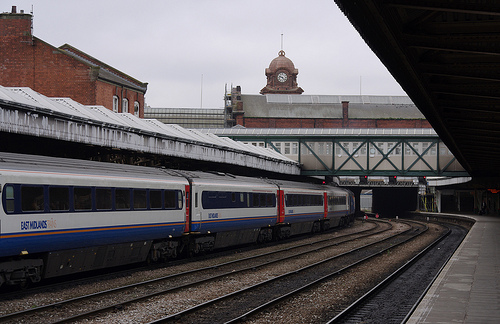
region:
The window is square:
[18, 183, 48, 215]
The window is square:
[43, 177, 73, 213]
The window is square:
[70, 181, 97, 212]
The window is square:
[90, 181, 117, 215]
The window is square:
[113, 185, 131, 213]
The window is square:
[130, 181, 155, 211]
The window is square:
[146, 184, 166, 215]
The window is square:
[161, 182, 181, 209]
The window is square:
[246, 188, 267, 210]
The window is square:
[264, 190, 276, 210]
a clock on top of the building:
[249, 41, 314, 118]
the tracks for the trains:
[241, 213, 427, 322]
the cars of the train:
[6, 139, 384, 259]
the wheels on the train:
[1, 245, 286, 262]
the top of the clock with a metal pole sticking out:
[274, 19, 295, 59]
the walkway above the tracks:
[264, 118, 484, 203]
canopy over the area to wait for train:
[342, 1, 498, 162]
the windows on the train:
[14, 187, 199, 232]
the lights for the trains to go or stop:
[323, 174, 444, 188]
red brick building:
[12, 7, 159, 137]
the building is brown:
[51, 61, 71, 80]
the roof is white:
[68, 99, 90, 115]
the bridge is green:
[341, 143, 359, 168]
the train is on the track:
[96, 257, 124, 282]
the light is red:
[391, 173, 398, 180]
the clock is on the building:
[276, 71, 289, 83]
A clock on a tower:
[276, 70, 291, 87]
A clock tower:
[261, 53, 303, 90]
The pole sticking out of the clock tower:
[273, 33, 287, 49]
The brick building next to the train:
[9, 7, 163, 115]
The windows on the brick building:
[111, 87, 148, 119]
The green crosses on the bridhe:
[248, 131, 462, 176]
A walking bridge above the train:
[213, 125, 454, 170]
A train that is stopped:
[16, 151, 361, 239]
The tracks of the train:
[164, 171, 441, 316]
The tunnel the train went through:
[325, 178, 411, 219]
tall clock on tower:
[248, 37, 323, 114]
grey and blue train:
[0, 169, 340, 239]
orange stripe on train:
[4, 208, 278, 239]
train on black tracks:
[30, 226, 379, 323]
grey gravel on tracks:
[117, 256, 218, 321]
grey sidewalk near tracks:
[421, 256, 499, 312]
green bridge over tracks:
[256, 140, 459, 188]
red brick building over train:
[0, 13, 152, 87]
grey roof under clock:
[248, 93, 409, 114]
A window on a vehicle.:
[20, 182, 45, 209]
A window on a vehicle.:
[49, 187, 70, 209]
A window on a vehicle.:
[73, 187, 93, 209]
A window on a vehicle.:
[96, 186, 114, 209]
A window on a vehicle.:
[133, 188, 148, 207]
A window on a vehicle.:
[163, 189, 178, 209]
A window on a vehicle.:
[253, 191, 260, 206]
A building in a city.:
[1, 3, 144, 117]